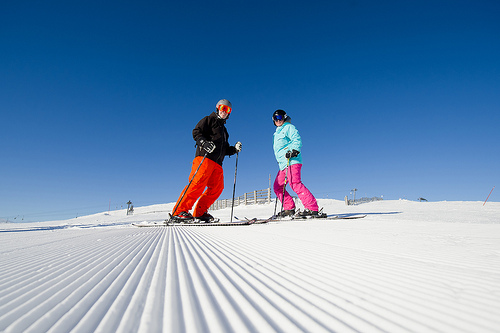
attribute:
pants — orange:
[170, 156, 225, 216]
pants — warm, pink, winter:
[142, 151, 257, 235]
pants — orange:
[184, 160, 217, 215]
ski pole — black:
[163, 146, 208, 221]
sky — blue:
[4, 1, 498, 198]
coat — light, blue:
[270, 122, 301, 169]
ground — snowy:
[2, 196, 499, 327]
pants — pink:
[273, 166, 328, 204]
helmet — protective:
[216, 97, 235, 114]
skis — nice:
[137, 217, 269, 232]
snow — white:
[311, 240, 404, 295]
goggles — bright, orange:
[217, 101, 233, 116]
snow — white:
[8, 194, 490, 331]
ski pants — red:
[177, 155, 226, 215]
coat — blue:
[269, 126, 304, 166]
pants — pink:
[273, 160, 316, 209]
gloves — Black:
[283, 148, 300, 160]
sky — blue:
[4, 5, 495, 227]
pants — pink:
[273, 159, 320, 219]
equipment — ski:
[164, 208, 223, 228]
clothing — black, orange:
[162, 110, 238, 218]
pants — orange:
[167, 157, 227, 220]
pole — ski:
[229, 140, 239, 224]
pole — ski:
[164, 137, 215, 225]